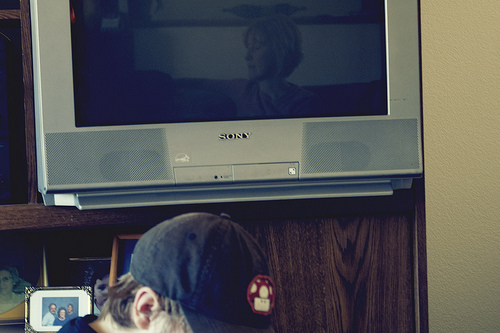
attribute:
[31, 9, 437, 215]
tv — sony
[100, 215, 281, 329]
hat — black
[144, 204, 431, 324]
entertainment center — wooden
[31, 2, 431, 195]
tv — grey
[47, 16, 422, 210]
tv — reflecting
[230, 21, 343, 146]
head — turned